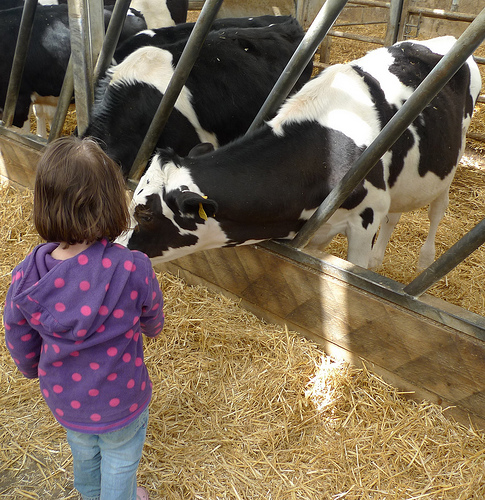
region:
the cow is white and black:
[142, 92, 394, 260]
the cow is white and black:
[102, 46, 481, 374]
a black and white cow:
[133, 30, 471, 293]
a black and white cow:
[49, 17, 302, 184]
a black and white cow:
[0, 0, 186, 142]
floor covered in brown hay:
[2, 196, 478, 496]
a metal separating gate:
[8, 0, 479, 412]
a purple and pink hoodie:
[7, 241, 162, 432]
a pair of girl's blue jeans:
[58, 410, 141, 497]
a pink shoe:
[132, 485, 148, 497]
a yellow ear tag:
[192, 201, 207, 223]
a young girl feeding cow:
[14, 132, 167, 497]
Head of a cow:
[132, 152, 226, 260]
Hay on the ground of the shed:
[192, 363, 400, 478]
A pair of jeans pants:
[62, 427, 136, 496]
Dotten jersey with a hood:
[25, 244, 149, 417]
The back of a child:
[17, 133, 171, 498]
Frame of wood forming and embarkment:
[355, 299, 422, 365]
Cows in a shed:
[5, 49, 479, 261]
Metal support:
[399, 8, 477, 140]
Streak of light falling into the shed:
[315, 267, 353, 411]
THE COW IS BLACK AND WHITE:
[95, 27, 484, 281]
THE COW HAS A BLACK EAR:
[162, 185, 223, 225]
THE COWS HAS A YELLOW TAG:
[192, 196, 211, 227]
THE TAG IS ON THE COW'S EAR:
[192, 198, 211, 231]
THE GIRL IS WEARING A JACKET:
[0, 237, 170, 435]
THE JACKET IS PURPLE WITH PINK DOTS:
[0, 232, 167, 431]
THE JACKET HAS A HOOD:
[2, 242, 165, 436]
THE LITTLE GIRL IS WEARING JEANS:
[55, 401, 143, 498]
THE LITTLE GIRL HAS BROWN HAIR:
[30, 129, 132, 250]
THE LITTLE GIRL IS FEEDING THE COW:
[4, 130, 161, 495]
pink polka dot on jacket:
[107, 396, 120, 408]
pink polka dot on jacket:
[87, 408, 100, 423]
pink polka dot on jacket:
[68, 369, 83, 389]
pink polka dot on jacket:
[50, 406, 72, 425]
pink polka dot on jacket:
[101, 341, 117, 361]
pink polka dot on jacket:
[48, 380, 62, 395]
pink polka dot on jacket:
[53, 300, 66, 317]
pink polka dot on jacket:
[48, 275, 68, 297]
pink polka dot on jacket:
[134, 356, 142, 369]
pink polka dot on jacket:
[126, 399, 139, 414]